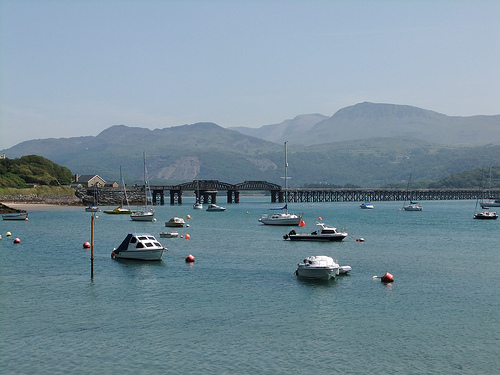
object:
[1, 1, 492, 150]
sky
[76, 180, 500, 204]
bridge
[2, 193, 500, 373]
water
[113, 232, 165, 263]
boat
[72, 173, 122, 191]
part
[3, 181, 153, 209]
bank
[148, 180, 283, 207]
section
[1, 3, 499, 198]
distance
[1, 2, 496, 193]
background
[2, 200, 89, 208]
beach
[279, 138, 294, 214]
sail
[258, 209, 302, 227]
boat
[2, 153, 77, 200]
terrain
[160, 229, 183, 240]
boat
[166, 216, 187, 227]
boat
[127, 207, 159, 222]
boat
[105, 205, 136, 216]
boat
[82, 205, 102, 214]
boat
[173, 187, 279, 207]
opening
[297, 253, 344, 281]
boat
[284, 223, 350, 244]
boat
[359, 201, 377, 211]
boat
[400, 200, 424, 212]
boat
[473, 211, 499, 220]
boat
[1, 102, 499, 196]
mountains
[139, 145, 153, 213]
sail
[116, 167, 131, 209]
sail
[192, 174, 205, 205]
sail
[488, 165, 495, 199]
sail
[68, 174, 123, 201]
property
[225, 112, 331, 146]
top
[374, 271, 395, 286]
floater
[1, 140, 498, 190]
forest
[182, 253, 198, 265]
bouy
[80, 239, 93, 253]
bouy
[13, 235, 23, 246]
bouy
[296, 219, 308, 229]
bouy